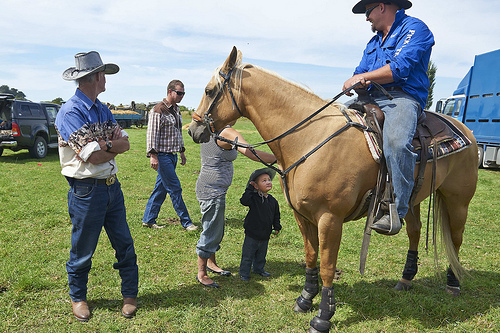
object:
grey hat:
[62, 51, 120, 81]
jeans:
[142, 152, 194, 228]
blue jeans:
[239, 235, 271, 281]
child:
[239, 167, 282, 281]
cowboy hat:
[246, 167, 276, 193]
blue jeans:
[343, 87, 424, 219]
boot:
[70, 298, 93, 321]